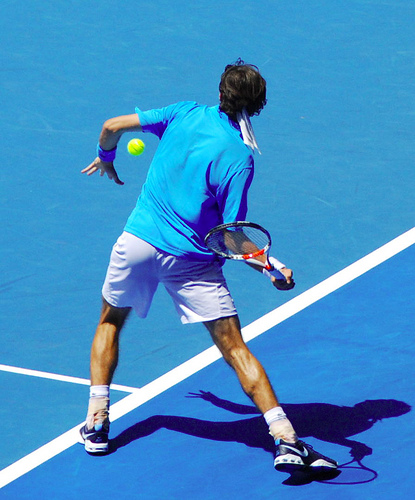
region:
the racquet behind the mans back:
[189, 143, 293, 295]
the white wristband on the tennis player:
[265, 251, 282, 283]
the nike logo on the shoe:
[282, 440, 312, 460]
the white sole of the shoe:
[274, 456, 337, 474]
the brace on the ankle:
[80, 396, 116, 427]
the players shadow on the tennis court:
[326, 380, 413, 490]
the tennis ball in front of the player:
[124, 130, 149, 162]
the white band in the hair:
[230, 108, 267, 153]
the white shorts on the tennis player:
[99, 237, 239, 327]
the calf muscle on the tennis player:
[225, 337, 265, 395]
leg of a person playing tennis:
[61, 233, 161, 456]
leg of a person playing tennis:
[175, 259, 343, 483]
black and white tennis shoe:
[70, 412, 115, 457]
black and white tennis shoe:
[271, 431, 342, 476]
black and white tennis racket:
[199, 212, 291, 296]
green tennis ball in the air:
[122, 135, 149, 160]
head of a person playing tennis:
[208, 53, 277, 121]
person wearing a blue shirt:
[72, 61, 342, 486]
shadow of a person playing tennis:
[92, 385, 411, 491]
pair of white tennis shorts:
[97, 229, 248, 330]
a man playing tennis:
[78, 62, 340, 480]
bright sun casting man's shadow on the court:
[93, 387, 408, 482]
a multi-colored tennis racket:
[201, 214, 297, 289]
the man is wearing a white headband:
[218, 60, 269, 148]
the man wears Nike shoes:
[76, 422, 341, 474]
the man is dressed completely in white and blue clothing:
[86, 63, 326, 477]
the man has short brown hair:
[218, 60, 267, 122]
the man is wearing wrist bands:
[93, 141, 285, 279]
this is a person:
[70, 57, 359, 495]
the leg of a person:
[175, 288, 365, 494]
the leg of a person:
[70, 263, 174, 463]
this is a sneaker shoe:
[263, 417, 348, 498]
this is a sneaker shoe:
[72, 394, 134, 472]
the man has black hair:
[198, 48, 283, 139]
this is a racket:
[203, 203, 286, 292]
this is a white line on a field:
[348, 207, 409, 265]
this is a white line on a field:
[118, 370, 202, 419]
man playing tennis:
[5, 3, 406, 484]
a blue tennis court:
[0, 3, 402, 489]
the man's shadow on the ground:
[106, 378, 400, 482]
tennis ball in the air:
[121, 135, 139, 149]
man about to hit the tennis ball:
[74, 58, 311, 466]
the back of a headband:
[230, 99, 257, 152]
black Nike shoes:
[271, 435, 343, 469]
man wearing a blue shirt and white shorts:
[88, 139, 259, 323]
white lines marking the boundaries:
[12, 241, 405, 490]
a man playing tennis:
[109, 76, 355, 406]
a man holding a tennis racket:
[128, 67, 305, 323]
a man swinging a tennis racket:
[155, 148, 327, 380]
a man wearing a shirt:
[176, 74, 254, 214]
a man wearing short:
[103, 232, 238, 350]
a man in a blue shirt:
[92, 60, 295, 429]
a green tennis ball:
[128, 140, 144, 154]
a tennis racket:
[209, 221, 284, 288]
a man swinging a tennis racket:
[89, 66, 312, 469]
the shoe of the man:
[75, 419, 118, 452]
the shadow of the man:
[107, 386, 413, 466]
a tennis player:
[91, 69, 331, 480]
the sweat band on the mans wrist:
[94, 144, 117, 161]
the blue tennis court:
[2, 19, 412, 489]